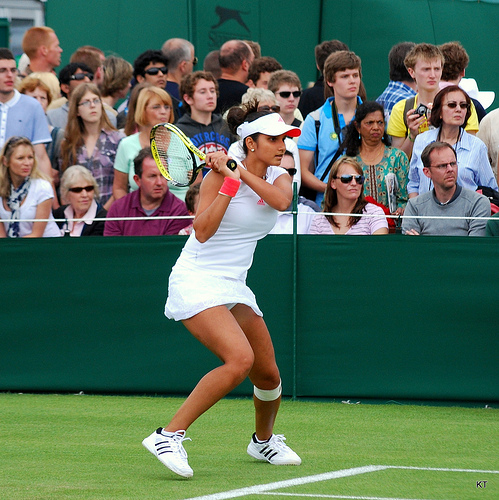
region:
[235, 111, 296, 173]
the head of a female tennis player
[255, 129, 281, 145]
the eyes of a female tennis player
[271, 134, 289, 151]
the nose of a female tennis player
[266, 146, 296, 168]
the mouth of a female tennis player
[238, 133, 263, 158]
the ear of a female tennis player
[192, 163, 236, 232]
the arm of a female tennis player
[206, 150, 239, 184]
the hands of a female tennis player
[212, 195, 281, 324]
the dress of a female tennis player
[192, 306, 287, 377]
the thighs of a female tennis player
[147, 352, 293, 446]
the shins of a female tennis player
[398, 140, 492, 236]
Spectator watching the match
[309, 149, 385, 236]
Spectator watching the match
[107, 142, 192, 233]
Spectator watching the match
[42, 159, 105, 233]
Spectator watching the match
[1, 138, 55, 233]
Spectator watching the match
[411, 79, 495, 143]
Spectator watching the match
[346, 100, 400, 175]
Spectator watching the match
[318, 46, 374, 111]
Spectator watching the match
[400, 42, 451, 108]
Spectator watching the match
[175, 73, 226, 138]
Spectator watching the match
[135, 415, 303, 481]
white tennis shoes with blue stripes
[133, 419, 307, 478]
tennis shoes has white pins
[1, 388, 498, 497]
floor of tennis court is green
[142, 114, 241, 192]
racket is yellow and black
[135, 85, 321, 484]
tennis player wears white clothes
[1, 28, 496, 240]
viewers in the bleachers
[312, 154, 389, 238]
woman wears black sunglasses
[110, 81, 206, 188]
the woman is blonde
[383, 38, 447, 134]
man holding a camera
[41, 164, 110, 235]
old woman has gray hair